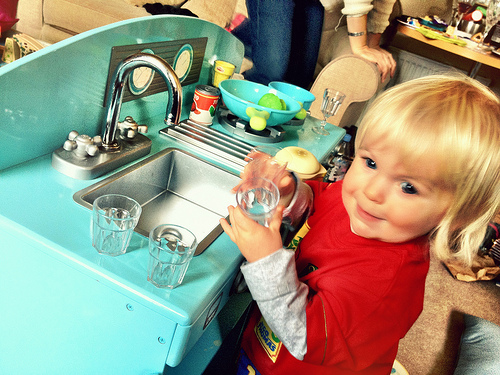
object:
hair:
[351, 71, 497, 267]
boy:
[229, 68, 496, 375]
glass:
[230, 175, 281, 224]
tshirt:
[243, 177, 432, 374]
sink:
[85, 150, 256, 248]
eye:
[396, 177, 422, 197]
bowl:
[218, 79, 301, 130]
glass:
[149, 224, 195, 286]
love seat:
[11, 0, 237, 63]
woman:
[227, 0, 403, 93]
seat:
[304, 0, 403, 124]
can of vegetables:
[189, 84, 223, 127]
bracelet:
[346, 30, 369, 39]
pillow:
[451, 311, 499, 374]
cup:
[213, 62, 235, 85]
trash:
[443, 249, 498, 283]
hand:
[218, 195, 284, 254]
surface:
[0, 73, 347, 318]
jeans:
[229, 0, 329, 83]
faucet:
[106, 52, 184, 160]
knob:
[59, 125, 104, 161]